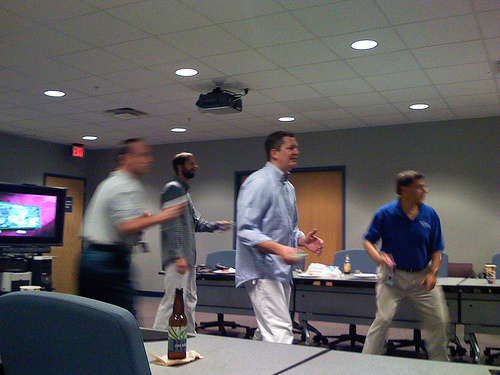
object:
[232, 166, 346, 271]
door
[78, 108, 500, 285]
wall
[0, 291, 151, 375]
chair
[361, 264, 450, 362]
pants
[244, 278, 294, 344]
pants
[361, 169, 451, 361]
guy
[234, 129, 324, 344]
guy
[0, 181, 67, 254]
television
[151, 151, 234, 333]
man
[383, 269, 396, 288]
remote control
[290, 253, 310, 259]
remote control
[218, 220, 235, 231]
remote control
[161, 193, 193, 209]
remote control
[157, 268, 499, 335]
gray table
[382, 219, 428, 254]
sea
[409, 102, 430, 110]
lighting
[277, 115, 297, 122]
lighting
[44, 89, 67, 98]
lighting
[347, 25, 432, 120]
shadow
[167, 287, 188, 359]
bottle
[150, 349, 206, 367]
napkin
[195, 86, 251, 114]
projection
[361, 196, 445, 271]
blue polo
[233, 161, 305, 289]
button down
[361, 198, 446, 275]
shirt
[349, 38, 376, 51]
light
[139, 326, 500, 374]
table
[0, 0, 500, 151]
ceiling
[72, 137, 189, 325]
man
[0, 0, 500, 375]
conference room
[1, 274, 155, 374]
left corner